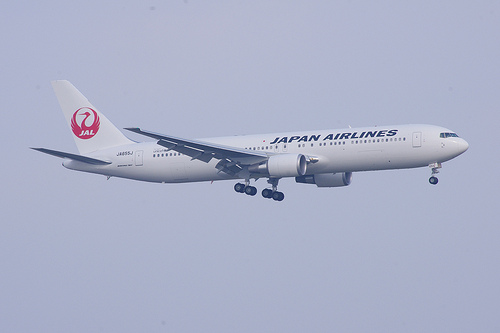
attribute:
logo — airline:
[69, 105, 101, 140]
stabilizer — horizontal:
[24, 143, 109, 166]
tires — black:
[230, 180, 286, 205]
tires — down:
[228, 182, 289, 200]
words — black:
[269, 127, 400, 144]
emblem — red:
[65, 103, 105, 143]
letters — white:
[76, 127, 98, 137]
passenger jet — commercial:
[35, 61, 476, 214]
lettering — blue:
[268, 133, 277, 145]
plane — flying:
[30, 78, 470, 202]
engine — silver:
[261, 152, 312, 181]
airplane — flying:
[38, 53, 498, 223]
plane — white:
[78, 91, 489, 221]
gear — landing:
[207, 152, 320, 206]